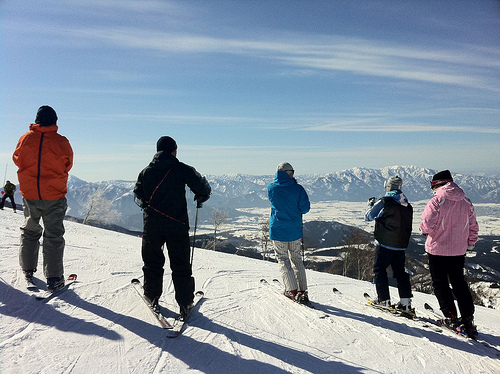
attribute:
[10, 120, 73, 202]
jacket — orange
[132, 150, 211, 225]
jacket — black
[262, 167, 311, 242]
jacket — blue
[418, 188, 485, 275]
jacket — pink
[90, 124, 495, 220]
mountain range — long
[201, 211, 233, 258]
tree — bare, leafless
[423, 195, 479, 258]
jacket — pink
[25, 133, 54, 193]
stripe — black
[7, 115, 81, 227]
jacket — orange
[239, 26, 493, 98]
clouds — white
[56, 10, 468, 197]
sky — blue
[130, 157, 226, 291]
ski outfit — black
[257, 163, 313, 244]
coat — blue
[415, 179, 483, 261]
coat — pink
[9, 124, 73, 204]
coat — orange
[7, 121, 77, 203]
coat — orange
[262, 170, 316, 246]
coat — blue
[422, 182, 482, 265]
coat — pink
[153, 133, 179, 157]
hat — black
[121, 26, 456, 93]
clouds — white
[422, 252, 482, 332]
pants — black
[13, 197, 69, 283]
pants — grey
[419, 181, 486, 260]
jacket — pink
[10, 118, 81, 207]
jacket — red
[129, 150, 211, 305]
snowsuit — black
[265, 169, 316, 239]
jacket — blue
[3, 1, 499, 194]
sky — blue